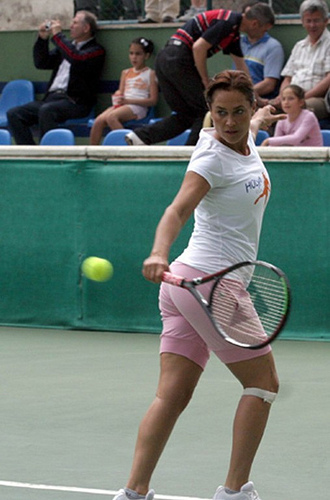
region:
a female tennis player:
[80, 69, 292, 498]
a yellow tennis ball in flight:
[79, 256, 112, 281]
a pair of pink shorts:
[156, 259, 271, 366]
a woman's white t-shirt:
[171, 125, 273, 286]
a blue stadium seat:
[41, 128, 71, 145]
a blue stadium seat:
[0, 128, 12, 143]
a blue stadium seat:
[101, 127, 128, 143]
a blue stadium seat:
[0, 76, 31, 121]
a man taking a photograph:
[7, 12, 104, 142]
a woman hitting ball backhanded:
[79, 69, 290, 498]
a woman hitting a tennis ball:
[83, 63, 289, 366]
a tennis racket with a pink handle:
[112, 248, 319, 357]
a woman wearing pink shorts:
[149, 131, 293, 377]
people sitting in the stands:
[59, 34, 324, 170]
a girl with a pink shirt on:
[258, 76, 327, 159]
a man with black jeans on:
[123, 33, 256, 151]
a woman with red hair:
[162, 37, 291, 211]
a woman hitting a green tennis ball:
[53, 77, 303, 370]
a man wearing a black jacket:
[19, 12, 129, 140]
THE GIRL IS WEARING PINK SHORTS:
[143, 251, 281, 370]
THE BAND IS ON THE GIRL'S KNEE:
[229, 376, 292, 400]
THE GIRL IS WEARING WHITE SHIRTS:
[107, 474, 272, 495]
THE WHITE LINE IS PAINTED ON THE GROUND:
[0, 476, 234, 497]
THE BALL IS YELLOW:
[67, 245, 115, 287]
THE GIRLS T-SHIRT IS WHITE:
[163, 121, 268, 288]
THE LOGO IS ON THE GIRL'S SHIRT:
[238, 169, 274, 206]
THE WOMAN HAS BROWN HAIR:
[198, 63, 260, 108]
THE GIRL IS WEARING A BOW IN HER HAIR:
[134, 33, 152, 48]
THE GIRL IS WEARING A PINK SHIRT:
[267, 106, 319, 149]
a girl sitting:
[122, 38, 160, 101]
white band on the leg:
[239, 378, 276, 402]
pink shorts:
[156, 287, 197, 339]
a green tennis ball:
[84, 252, 114, 280]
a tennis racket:
[201, 273, 299, 353]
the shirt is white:
[214, 206, 244, 254]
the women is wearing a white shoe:
[218, 481, 263, 498]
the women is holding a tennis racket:
[137, 251, 172, 276]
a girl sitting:
[278, 83, 319, 143]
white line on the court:
[31, 474, 67, 497]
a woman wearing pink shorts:
[153, 256, 265, 371]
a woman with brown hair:
[216, 72, 260, 117]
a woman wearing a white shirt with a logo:
[184, 98, 271, 281]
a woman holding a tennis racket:
[128, 246, 298, 376]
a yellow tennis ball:
[77, 248, 134, 287]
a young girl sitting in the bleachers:
[96, 27, 163, 138]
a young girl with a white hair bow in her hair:
[122, 32, 159, 75]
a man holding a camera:
[31, 9, 97, 45]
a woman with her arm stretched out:
[203, 80, 285, 164]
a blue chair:
[34, 126, 76, 154]